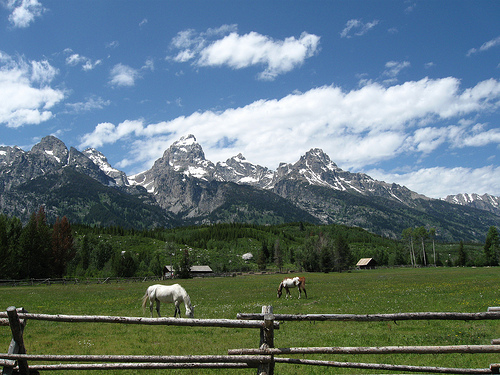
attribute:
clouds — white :
[11, 22, 486, 152]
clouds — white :
[167, 27, 319, 83]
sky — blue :
[352, 26, 462, 113]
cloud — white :
[196, 32, 319, 79]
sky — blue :
[4, 0, 497, 202]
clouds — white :
[279, 87, 402, 164]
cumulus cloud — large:
[171, 20, 314, 89]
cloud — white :
[110, 62, 140, 87]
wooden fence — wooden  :
[3, 304, 498, 371]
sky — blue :
[9, 7, 496, 133]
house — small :
[349, 242, 377, 271]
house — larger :
[162, 263, 214, 280]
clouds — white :
[93, 78, 496, 158]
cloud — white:
[174, 24, 323, 81]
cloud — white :
[106, 62, 136, 88]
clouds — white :
[5, 1, 46, 26]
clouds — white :
[105, 25, 465, 140]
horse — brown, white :
[274, 273, 311, 301]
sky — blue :
[71, 42, 208, 117]